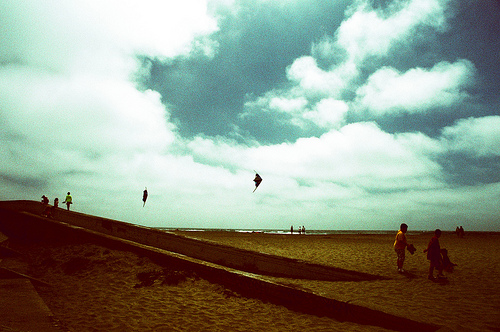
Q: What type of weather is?
A: It is cloudy.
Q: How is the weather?
A: It is cloudy.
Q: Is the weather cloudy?
A: Yes, it is cloudy.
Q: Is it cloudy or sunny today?
A: It is cloudy.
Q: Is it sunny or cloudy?
A: It is cloudy.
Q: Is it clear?
A: No, it is cloudy.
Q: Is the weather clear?
A: No, it is cloudy.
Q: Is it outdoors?
A: Yes, it is outdoors.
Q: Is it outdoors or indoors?
A: It is outdoors.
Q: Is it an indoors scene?
A: No, it is outdoors.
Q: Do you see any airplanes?
A: No, there are no airplanes.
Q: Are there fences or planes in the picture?
A: No, there are no planes or fences.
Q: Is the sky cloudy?
A: Yes, the sky is cloudy.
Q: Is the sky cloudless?
A: No, the sky is cloudy.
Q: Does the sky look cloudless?
A: No, the sky is cloudy.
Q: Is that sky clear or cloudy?
A: The sky is cloudy.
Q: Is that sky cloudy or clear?
A: The sky is cloudy.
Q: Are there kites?
A: Yes, there is a kite.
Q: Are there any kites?
A: Yes, there is a kite.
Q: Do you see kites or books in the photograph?
A: Yes, there is a kite.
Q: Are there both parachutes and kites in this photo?
A: No, there is a kite but no parachutes.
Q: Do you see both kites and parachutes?
A: No, there is a kite but no parachutes.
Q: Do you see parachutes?
A: No, there are no parachutes.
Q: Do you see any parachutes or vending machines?
A: No, there are no parachutes or vending machines.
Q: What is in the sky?
A: The kite is in the sky.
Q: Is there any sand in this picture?
A: Yes, there is sand.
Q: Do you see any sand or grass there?
A: Yes, there is sand.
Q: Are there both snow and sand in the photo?
A: No, there is sand but no snow.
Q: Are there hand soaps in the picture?
A: No, there are no hand soaps.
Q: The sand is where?
A: The sand is on the beach.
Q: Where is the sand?
A: The sand is on the beach.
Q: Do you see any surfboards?
A: No, there are no surfboards.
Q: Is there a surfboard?
A: No, there are no surfboards.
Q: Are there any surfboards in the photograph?
A: No, there are no surfboards.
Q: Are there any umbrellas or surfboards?
A: No, there are no surfboards or umbrellas.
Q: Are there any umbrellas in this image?
A: No, there are no umbrellas.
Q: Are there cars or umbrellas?
A: No, there are no umbrellas or cars.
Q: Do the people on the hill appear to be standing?
A: Yes, the people are standing.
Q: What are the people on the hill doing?
A: The people are standing.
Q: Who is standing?
A: The people are standing.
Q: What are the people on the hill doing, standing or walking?
A: The people are standing.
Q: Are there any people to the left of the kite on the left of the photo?
A: Yes, there are people to the left of the kite.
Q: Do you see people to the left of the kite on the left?
A: Yes, there are people to the left of the kite.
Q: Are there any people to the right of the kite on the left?
A: No, the people are to the left of the kite.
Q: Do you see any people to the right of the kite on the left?
A: No, the people are to the left of the kite.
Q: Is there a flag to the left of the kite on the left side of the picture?
A: No, there are people to the left of the kite.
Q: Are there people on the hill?
A: Yes, there are people on the hill.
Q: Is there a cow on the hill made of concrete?
A: No, there are people on the hill.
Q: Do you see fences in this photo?
A: No, there are no fences.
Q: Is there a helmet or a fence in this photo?
A: No, there are no fences or helmets.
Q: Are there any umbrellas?
A: No, there are no umbrellas.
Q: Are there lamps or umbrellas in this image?
A: No, there are no umbrellas or lamps.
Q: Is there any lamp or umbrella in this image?
A: No, there are no umbrellas or lamps.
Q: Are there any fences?
A: No, there are no fences.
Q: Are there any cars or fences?
A: No, there are no fences or cars.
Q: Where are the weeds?
A: The weeds are in the sand.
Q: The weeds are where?
A: The weeds are on the hill.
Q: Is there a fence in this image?
A: No, there are no fences.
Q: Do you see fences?
A: No, there are no fences.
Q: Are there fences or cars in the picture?
A: No, there are no fences or cars.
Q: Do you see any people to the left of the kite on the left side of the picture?
A: Yes, there is a person to the left of the kite.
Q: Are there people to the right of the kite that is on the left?
A: No, the person is to the left of the kite.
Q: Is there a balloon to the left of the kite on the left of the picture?
A: No, there is a person to the left of the kite.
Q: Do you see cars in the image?
A: No, there are no cars.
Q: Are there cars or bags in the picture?
A: No, there are no cars or bags.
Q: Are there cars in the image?
A: No, there are no cars.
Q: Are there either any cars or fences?
A: No, there are no cars or fences.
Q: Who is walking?
A: The people are walking.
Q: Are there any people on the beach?
A: Yes, there are people on the beach.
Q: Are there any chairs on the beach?
A: No, there are people on the beach.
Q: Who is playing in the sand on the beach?
A: The people are playing in the sand.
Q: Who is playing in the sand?
A: The people are playing in the sand.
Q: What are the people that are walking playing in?
A: The people are playing in the sand.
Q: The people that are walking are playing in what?
A: The people are playing in the sand.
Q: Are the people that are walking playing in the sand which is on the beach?
A: Yes, the people are playing in the sand.